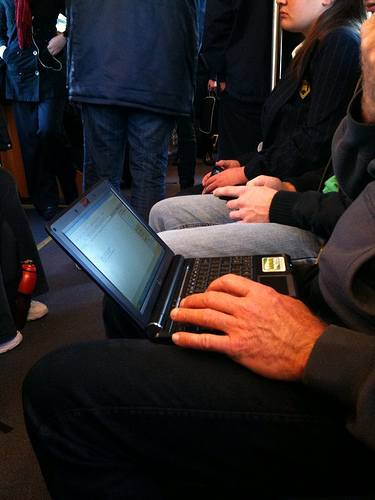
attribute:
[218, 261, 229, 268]
key — black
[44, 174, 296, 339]
laptop — open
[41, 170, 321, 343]
laptop — black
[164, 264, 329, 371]
hand — man's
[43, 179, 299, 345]
lap top — black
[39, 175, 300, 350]
laptop — black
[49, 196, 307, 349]
laptop — black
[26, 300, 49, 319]
sneaker — white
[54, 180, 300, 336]
lap top — black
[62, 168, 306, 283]
laptop — black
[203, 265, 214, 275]
key — black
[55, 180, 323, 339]
lap top — black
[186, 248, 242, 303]
key — black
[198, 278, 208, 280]
key — black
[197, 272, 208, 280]
key — black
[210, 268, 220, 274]
key — black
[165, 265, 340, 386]
hand — man's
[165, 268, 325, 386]
hand — man's